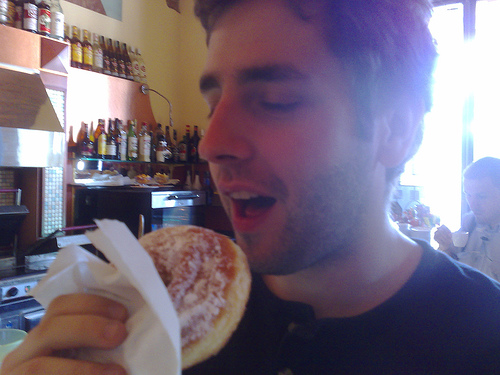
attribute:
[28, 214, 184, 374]
napkin — white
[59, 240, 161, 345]
napkin — white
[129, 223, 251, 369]
donut — covered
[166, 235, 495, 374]
black shirt — round necked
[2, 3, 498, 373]
man — open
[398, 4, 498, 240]
sun — bright white, streaming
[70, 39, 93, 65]
labels — yellow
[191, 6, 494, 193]
hair — salt and pepper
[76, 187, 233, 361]
cup — white 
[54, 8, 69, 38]
cup — white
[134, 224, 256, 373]
doughnut — sugar crusted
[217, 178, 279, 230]
mouth — open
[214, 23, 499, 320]
man — holding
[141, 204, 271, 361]
doughnut — sugar